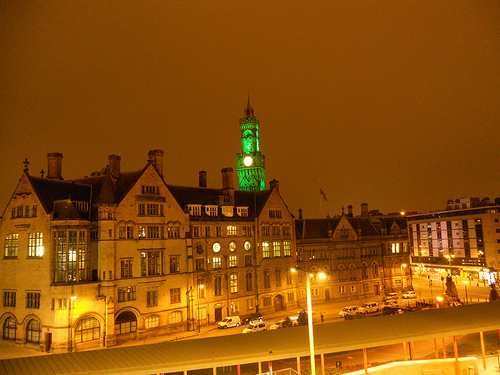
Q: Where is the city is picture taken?
A: A city.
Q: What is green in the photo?
A: A clock tower.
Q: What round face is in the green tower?
A: A clock.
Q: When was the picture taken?
A: The evening.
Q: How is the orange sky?
A: Cloudless.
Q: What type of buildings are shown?
A: Gothic.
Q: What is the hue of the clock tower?
A: Green.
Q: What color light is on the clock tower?
A: Green.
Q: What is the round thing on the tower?
A: Clock.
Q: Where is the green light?
A: Clock tower.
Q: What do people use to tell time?
A: Clocks.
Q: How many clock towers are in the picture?
A: One.